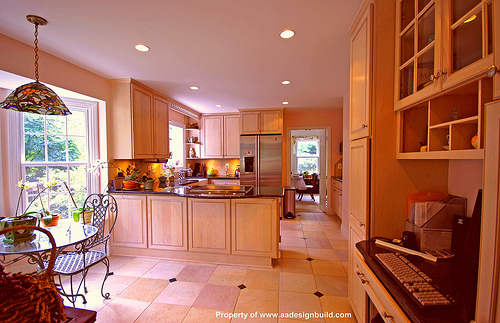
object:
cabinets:
[389, 0, 442, 111]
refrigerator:
[240, 137, 282, 197]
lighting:
[281, 79, 291, 88]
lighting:
[280, 99, 290, 106]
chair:
[37, 192, 117, 304]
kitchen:
[106, 0, 351, 269]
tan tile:
[310, 257, 346, 276]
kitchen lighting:
[212, 104, 220, 108]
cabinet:
[230, 202, 272, 253]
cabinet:
[130, 85, 155, 156]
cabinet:
[200, 115, 225, 157]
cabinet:
[261, 111, 283, 133]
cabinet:
[347, 15, 373, 141]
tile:
[280, 272, 317, 292]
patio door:
[19, 107, 97, 215]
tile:
[190, 283, 238, 313]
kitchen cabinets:
[186, 199, 232, 255]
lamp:
[0, 14, 72, 116]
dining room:
[292, 134, 323, 202]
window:
[69, 136, 89, 163]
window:
[167, 123, 189, 168]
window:
[294, 135, 320, 156]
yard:
[23, 111, 87, 221]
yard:
[297, 140, 317, 155]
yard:
[297, 157, 317, 174]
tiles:
[232, 288, 278, 315]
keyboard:
[371, 252, 458, 312]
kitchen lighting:
[278, 28, 293, 40]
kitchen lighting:
[134, 44, 149, 52]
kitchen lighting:
[189, 83, 199, 92]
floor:
[62, 208, 357, 322]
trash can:
[284, 186, 297, 220]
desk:
[353, 239, 500, 323]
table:
[0, 219, 99, 312]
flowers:
[15, 177, 30, 191]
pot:
[40, 213, 60, 225]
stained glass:
[1, 80, 71, 115]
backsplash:
[203, 158, 241, 180]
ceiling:
[0, 0, 363, 114]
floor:
[54, 193, 362, 323]